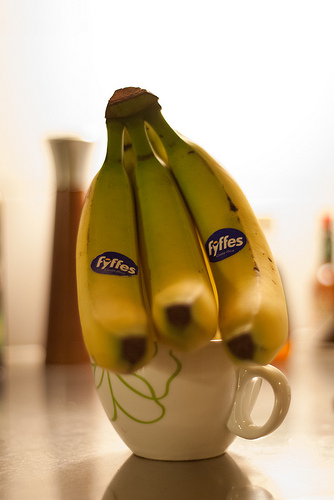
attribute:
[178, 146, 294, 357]
banana —   bunch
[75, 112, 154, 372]
banana — three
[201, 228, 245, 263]
label — blue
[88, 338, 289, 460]
cup — white 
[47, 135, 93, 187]
lid — white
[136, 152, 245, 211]
bananas — yellow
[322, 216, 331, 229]
lid — red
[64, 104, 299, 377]
bananas — yellow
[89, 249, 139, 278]
sticker — oval, blue